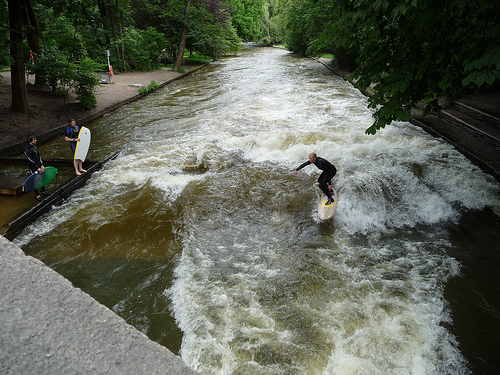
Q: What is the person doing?
A: Surfing.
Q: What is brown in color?
A: The water.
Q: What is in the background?
A: Trees.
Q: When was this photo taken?
A: During the daytime.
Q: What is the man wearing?
A: A wet suit.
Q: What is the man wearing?
A: A black wetsuit.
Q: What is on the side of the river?
A: A concrete ledge.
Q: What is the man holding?
A: A white board.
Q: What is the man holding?
A: A green and blue board.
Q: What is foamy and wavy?
A: Water.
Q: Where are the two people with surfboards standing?
A: Shore.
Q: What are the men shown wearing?
A: Wetsuits.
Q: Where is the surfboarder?
A: In river.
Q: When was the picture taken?
A: Daytime.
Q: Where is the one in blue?
A: To the left of the surfer.